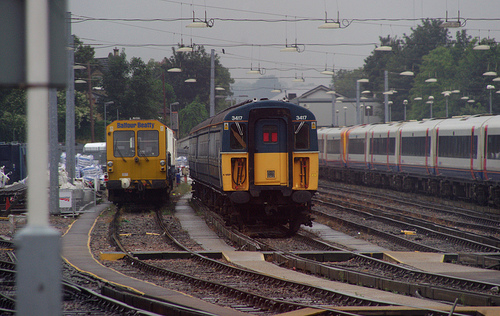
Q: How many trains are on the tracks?
A: Three.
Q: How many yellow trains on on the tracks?
A: Two.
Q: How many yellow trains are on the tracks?
A: Two.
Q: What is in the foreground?
A: A bunch of train tracks.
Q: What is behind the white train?
A: Green trees.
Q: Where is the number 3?
A: On the train.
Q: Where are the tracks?
A: On the ground.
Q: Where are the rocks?
A: On the ground.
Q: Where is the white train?
A: On the tracks.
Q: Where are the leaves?
A: On the trees.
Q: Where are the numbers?
A: On the train.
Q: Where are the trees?
A: Behind the trains.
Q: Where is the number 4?
A: On the train.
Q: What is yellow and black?
A: The train.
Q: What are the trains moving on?
A: Tracks.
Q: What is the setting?
A: A train station.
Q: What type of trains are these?
A: Passenger.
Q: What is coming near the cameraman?
A: A train.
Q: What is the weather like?
A: Overcast.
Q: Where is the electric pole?
A: Near the railroad.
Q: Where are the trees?
A: Near the horizon.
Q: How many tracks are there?
A: Four.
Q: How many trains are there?
A: Three.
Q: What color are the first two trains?
A: Yellow.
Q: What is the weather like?
A: Cloudy.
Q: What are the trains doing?
A: Parked.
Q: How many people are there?
A: None.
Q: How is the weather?
A: Mild.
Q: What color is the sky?
A: Gray.